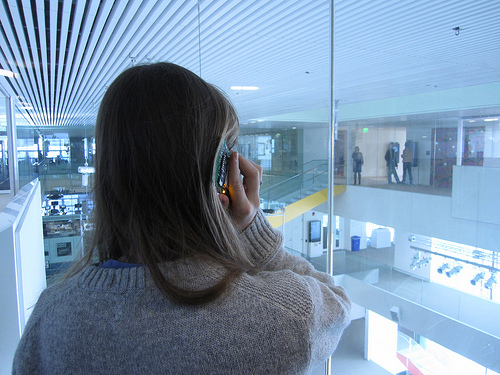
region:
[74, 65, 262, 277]
the head of a woman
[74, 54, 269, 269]
the hair of a woman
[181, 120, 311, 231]
a woman on a phone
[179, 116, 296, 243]
the hand of a woman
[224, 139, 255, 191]
the finger of a woman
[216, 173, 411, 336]
the arm of a woman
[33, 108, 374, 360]
a woman wearing a sweater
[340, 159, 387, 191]
the legs of a woman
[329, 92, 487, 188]
people in the background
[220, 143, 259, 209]
the index finger of a woman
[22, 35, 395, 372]
person talking on cell phone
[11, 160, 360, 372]
person wearing tan sweater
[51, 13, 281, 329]
person with brown hair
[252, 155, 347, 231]
yellow trim on strairs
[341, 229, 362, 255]
blue trash can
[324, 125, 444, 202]
group of people standing together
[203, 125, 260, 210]
cell phone is black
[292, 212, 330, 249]
sign attached to wall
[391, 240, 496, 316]
white light fixtures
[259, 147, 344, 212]
silver arm rail on stairs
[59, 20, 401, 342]
a woman is looking at office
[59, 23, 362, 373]
the woman has a sweater on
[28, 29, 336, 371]
the woman has long hair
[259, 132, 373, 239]
the stairway is yellow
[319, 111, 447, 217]
people on other side of office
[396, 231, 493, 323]
studio lights hanging from bar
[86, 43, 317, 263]
the woman has a phone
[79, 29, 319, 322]
holding the phone to your ear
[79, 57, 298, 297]
she is making a call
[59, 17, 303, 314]
the light on the phone is on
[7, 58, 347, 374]
woman who is on the phone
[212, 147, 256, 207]
phone help up to the ear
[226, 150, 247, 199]
finger on the phone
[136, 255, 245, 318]
lock of hair resting on the upper back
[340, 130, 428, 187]
group of people standing around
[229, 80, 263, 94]
light on the ceiling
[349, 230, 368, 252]
blue bin against the wall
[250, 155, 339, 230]
a staircase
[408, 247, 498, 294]
a row of lights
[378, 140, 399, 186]
person leaning against the wall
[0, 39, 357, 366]
Woman is talking on cell phone.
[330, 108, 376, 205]
Woman standing in the hallway.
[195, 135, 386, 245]
Yellow stairs near woman in hallway.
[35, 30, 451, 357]
Woman looking out glass window.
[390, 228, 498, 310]
Track lighting attached to bottom of third floor.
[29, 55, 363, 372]
Woman wearing a grey sweater.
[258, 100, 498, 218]
Hallway has glass interior wall.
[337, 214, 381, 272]
Blue garbage can on second floor.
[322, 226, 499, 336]
Hallway has tan colored carpeting.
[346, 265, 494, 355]
Speaker hanging on side of second floor.